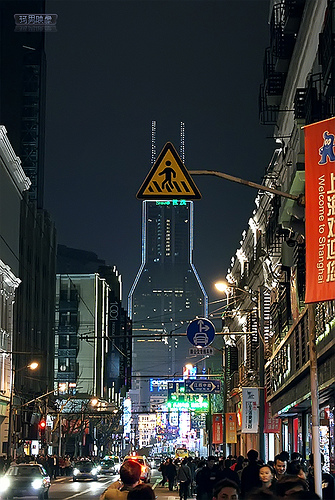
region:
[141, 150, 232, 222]
a sign on a pole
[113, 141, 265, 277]
a sign on a metal pole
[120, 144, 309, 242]
a pole with a sign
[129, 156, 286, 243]
a metal pole with a sign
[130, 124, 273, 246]
a street sign on a pole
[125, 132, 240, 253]
a street sign on a metal pole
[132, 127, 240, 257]
a pole with a street sign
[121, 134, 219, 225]
a metal pole with street sign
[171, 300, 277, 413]
a blue sign on the pole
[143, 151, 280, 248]
a yellow sign on a pole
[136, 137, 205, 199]
HANGING YELLOW PEDESTRIAN SIGN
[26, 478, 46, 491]
HEADLIGHT OF SMALL CAR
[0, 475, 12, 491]
HEADLIGHT OF SMALL CAR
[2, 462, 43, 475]
FRONT WINDSHIELD OF SMALL CAR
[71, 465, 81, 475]
HEADLIGHT OF SMALL CAR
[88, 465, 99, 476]
HEADLIGHT OF SMALL CAR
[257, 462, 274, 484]
HEAD OF PERSON WALKING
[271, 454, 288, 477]
HEAD OF PERSON WALKING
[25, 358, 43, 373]
OVERHEAD HIGH STREET LIGHT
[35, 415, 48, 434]
RED TRAFFIC STREET LIGHT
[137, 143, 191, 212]
black and yellow sign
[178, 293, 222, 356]
blue and white sign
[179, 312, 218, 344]
white arrows on sign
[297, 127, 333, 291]
red and white banner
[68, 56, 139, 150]
sky is dark blue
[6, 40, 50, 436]
black and tall building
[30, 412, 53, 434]
traffic light is red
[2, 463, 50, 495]
white lights on car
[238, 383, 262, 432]
white and black banner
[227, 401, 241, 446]
orange and yellow banner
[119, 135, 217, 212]
this is a crosswalk sign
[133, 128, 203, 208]
a sign signaling a pedestrian crossing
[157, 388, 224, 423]
bright neon green lights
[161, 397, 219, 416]
a bright neon sign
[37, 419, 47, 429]
this is a red stoplight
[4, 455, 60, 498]
a car in the street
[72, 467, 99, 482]
the bright headlights of a car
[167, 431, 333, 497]
pedestrians on a sidewalk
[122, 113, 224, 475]
a tall sky scraper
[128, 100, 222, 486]
there are lights on the edge of the building